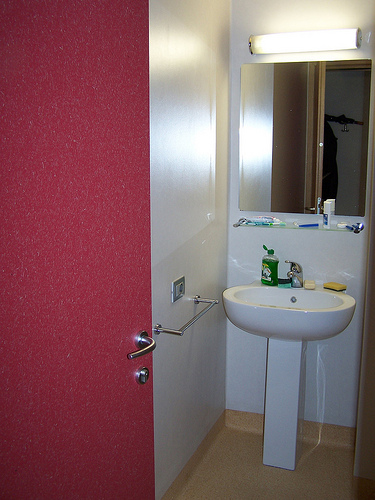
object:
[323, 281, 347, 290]
sponge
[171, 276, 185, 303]
lightswitch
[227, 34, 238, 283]
wall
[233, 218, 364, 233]
shelf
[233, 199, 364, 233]
items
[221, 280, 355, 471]
pedestal sink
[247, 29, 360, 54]
light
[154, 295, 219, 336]
towel bar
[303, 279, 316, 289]
soap bar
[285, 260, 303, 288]
faucet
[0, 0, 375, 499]
bathroom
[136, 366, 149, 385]
key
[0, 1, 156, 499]
door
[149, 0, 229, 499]
wall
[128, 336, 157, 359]
door knob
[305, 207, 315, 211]
door knob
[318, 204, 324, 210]
door knob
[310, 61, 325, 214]
door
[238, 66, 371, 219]
mirror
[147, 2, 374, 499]
wall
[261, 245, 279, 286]
soap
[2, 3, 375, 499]
residence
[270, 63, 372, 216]
closet inside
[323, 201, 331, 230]
item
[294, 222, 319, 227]
item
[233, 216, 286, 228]
item